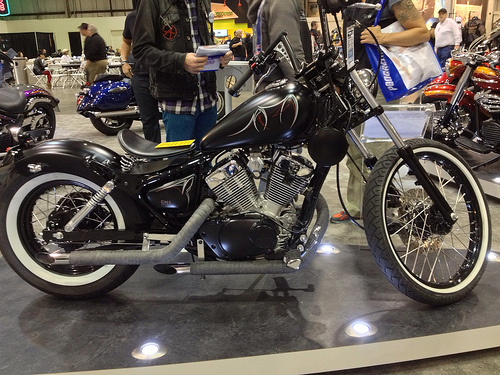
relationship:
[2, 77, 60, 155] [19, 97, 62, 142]
bike has tire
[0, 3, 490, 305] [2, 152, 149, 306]
bike has wheel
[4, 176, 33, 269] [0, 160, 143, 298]
stripe on tire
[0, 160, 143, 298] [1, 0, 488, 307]
tire on motorcycle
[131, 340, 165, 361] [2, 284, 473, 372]
light on floor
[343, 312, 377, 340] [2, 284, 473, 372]
light on floor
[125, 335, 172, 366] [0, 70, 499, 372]
light on floor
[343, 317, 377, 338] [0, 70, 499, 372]
light on floor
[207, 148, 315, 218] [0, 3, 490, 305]
motor on a bike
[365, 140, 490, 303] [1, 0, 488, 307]
tire on a motorcycle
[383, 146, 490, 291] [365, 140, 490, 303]
whitewall on a tire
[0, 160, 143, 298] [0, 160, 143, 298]
tire on a tire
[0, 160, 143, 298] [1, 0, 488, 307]
tire on a motorcycle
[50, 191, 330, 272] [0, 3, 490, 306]
exhaust pipes on a bike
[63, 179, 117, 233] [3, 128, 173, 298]
shock absorbers on back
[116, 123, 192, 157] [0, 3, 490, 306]
seat on bike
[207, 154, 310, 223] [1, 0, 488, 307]
motor on motorcycle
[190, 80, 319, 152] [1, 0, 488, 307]
gas tank on motorcycle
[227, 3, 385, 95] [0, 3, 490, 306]
handle bars on bike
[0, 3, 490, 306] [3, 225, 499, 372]
bike on display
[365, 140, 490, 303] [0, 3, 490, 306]
tire on bike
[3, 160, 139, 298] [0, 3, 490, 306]
tire on bike